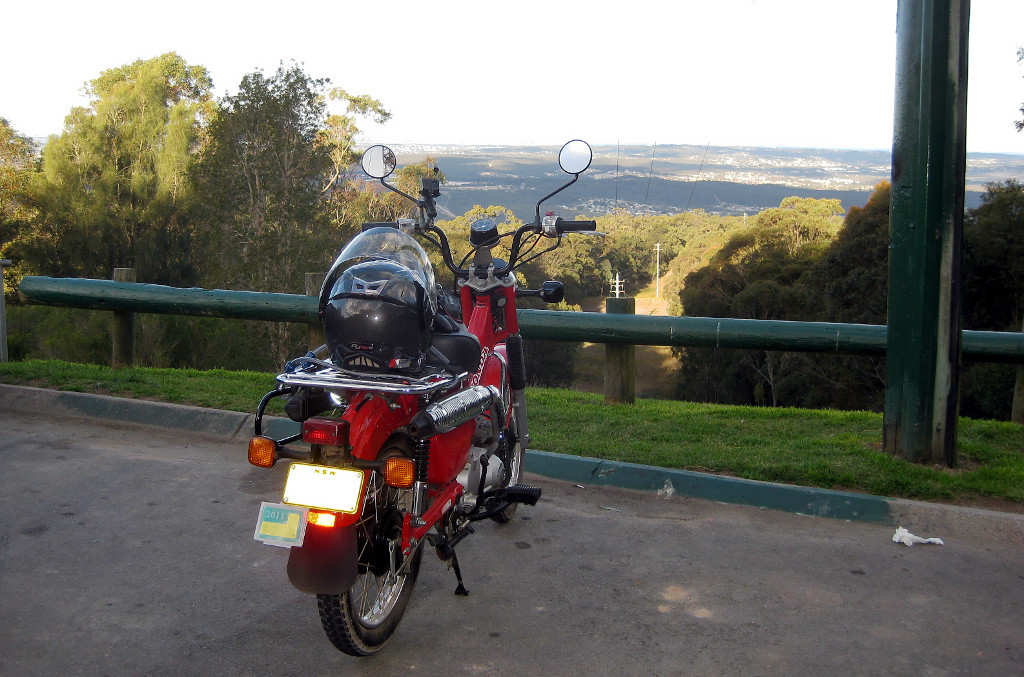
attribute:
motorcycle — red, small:
[241, 141, 627, 673]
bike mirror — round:
[359, 140, 395, 172]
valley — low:
[429, 140, 875, 217]